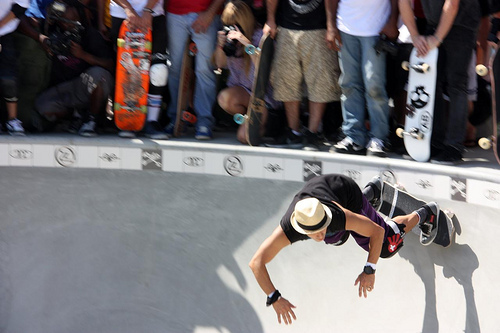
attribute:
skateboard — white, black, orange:
[110, 10, 153, 133]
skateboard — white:
[400, 30, 446, 165]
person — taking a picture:
[210, 2, 265, 143]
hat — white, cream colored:
[285, 196, 336, 242]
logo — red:
[384, 232, 406, 258]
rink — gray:
[4, 129, 499, 331]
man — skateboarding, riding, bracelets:
[247, 178, 443, 326]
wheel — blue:
[233, 110, 248, 128]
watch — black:
[362, 263, 375, 278]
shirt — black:
[276, 170, 363, 246]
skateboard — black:
[364, 177, 461, 258]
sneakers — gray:
[250, 125, 333, 152]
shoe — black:
[429, 140, 465, 171]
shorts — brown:
[266, 22, 343, 110]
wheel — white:
[473, 63, 488, 79]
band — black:
[140, 6, 160, 18]